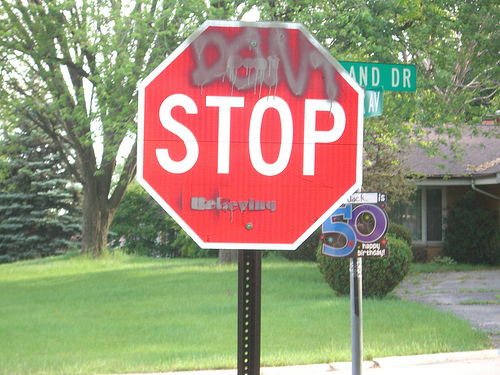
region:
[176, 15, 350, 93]
grafitti on a traffic sign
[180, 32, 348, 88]
grafitti on a stop sign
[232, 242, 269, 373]
post with multiple holes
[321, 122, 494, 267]
one story house in the background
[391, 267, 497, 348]
concrete driveway for the house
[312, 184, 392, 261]
sign for Jack's birthday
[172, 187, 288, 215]
second word of the grafitti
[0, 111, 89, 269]
a blue spruce tree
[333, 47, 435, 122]
green and white street sign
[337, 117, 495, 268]
house with composition roof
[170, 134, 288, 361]
a sign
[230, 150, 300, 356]
a sign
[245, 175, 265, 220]
a sign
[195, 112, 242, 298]
a sign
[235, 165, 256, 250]
a sign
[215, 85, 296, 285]
a sign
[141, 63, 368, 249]
Stop sign is red and white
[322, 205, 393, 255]
Sign that says Jack is 50 happy birthday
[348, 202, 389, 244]
The number 0 is purple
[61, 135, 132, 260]
A tree in the front yard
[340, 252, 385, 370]
A metal pole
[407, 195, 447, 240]
A window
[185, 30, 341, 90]
Tagging on the stop sign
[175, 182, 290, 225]
The words believing on the stop sign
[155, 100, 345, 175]
Letters are white on stop sign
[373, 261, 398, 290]
A green bush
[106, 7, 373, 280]
A red stop sign.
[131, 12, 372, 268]
Graffiti on a stop sign.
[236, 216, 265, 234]
Bolt on bottomvof stop sign.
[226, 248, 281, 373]
Black support pole for stop sign.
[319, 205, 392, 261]
The number 50 in purple and blue.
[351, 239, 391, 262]
The words happy birthday in white letters.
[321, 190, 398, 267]
A happy birthday sign.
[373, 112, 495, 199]
Light colored roof on house.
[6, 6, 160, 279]
A large tree with green leaves.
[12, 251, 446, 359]
Green grass in the yard.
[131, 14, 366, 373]
a red and white sign near a sidewalk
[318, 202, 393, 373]
a sign with a number by the street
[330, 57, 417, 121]
a street sign has letters on it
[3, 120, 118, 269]
an evergreen tree is in the yard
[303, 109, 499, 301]
a house is behind the signs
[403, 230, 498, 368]
the house has a driveway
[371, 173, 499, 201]
a gutter system is on the house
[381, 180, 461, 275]
windows are in the front of the house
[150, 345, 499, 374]
a curb is in front of the house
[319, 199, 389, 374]
the number fifty is on a sign